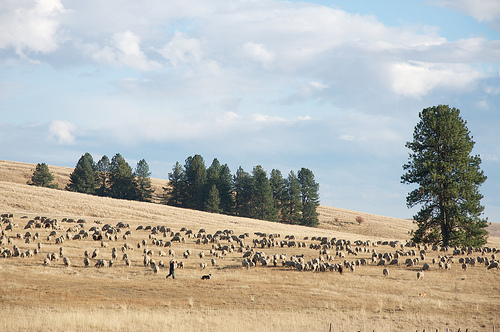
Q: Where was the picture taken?
A: It was taken at the field.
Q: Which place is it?
A: It is a field.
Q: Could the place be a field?
A: Yes, it is a field.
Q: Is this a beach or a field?
A: It is a field.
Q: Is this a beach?
A: No, it is a field.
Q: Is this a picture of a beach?
A: No, the picture is showing a field.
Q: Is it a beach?
A: No, it is a field.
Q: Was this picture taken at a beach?
A: No, the picture was taken in a field.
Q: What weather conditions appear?
A: It is cloudy.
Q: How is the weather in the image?
A: It is cloudy.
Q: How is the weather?
A: It is cloudy.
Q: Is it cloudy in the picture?
A: Yes, it is cloudy.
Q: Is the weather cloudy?
A: Yes, it is cloudy.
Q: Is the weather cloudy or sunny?
A: It is cloudy.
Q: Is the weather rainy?
A: No, it is cloudy.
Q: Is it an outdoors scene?
A: Yes, it is outdoors.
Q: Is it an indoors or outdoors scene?
A: It is outdoors.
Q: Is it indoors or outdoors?
A: It is outdoors.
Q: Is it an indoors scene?
A: No, it is outdoors.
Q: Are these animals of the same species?
A: No, they are sheep and dogs.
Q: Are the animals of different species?
A: Yes, they are sheep and dogs.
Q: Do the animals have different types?
A: Yes, they are sheep and dogs.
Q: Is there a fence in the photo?
A: No, there are no fences.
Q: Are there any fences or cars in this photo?
A: No, there are no fences or cars.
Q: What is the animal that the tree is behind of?
A: The animal is a sheep.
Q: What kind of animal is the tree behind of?
A: The tree is behind the sheep.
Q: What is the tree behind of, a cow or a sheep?
A: The tree is behind a sheep.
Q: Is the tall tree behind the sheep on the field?
A: Yes, the tree is behind the sheep.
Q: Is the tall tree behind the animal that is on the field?
A: Yes, the tree is behind the sheep.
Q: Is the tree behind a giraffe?
A: No, the tree is behind the sheep.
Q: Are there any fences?
A: No, there are no fences.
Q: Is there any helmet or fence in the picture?
A: No, there are no fences or helmets.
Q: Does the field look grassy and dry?
A: No, the field is dry but bare.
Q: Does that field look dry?
A: Yes, the field is dry.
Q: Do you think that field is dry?
A: Yes, the field is dry.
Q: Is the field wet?
A: No, the field is dry.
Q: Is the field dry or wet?
A: The field is dry.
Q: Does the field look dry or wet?
A: The field is dry.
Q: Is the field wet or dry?
A: The field is dry.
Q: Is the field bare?
A: Yes, the field is bare.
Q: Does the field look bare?
A: Yes, the field is bare.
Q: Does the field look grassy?
A: No, the field is bare.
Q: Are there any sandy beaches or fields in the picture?
A: No, there is a field but it is bare.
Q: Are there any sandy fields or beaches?
A: No, there is a field but it is bare.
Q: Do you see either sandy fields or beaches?
A: No, there is a field but it is bare.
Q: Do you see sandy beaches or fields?
A: No, there is a field but it is bare.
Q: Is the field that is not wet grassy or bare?
A: The field is bare.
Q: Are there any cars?
A: No, there are no cars.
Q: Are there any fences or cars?
A: No, there are no cars or fences.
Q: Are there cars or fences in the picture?
A: No, there are no cars or fences.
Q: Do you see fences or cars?
A: No, there are no cars or fences.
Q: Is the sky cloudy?
A: Yes, the sky is cloudy.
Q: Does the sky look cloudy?
A: Yes, the sky is cloudy.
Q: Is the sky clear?
A: No, the sky is cloudy.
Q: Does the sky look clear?
A: No, the sky is cloudy.